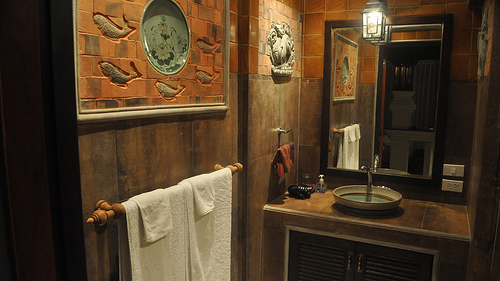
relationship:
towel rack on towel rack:
[88, 162, 244, 226] [82, 160, 250, 234]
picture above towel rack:
[70, 2, 233, 128] [82, 160, 250, 234]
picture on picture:
[72, 2, 230, 123] [70, 2, 233, 128]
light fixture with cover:
[359, 4, 390, 45] [355, 0, 390, 44]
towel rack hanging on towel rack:
[275, 127, 296, 151] [267, 127, 298, 152]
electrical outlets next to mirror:
[442, 179, 463, 193] [320, 18, 442, 192]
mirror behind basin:
[320, 18, 442, 192] [333, 185, 403, 219]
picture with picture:
[70, 2, 233, 128] [72, 2, 230, 123]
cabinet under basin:
[276, 222, 442, 280] [333, 185, 403, 219]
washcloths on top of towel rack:
[125, 169, 223, 240] [88, 162, 244, 226]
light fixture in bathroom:
[359, 4, 390, 45] [2, 2, 499, 280]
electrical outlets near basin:
[441, 181, 464, 193] [333, 185, 403, 219]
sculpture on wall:
[266, 23, 296, 76] [251, 0, 303, 281]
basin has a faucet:
[333, 185, 403, 219] [359, 165, 377, 206]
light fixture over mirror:
[359, 4, 390, 45] [320, 18, 442, 192]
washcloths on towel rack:
[125, 169, 223, 240] [82, 160, 250, 234]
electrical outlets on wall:
[441, 181, 464, 193] [297, 0, 469, 210]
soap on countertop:
[312, 173, 329, 194] [257, 183, 477, 240]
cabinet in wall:
[276, 222, 442, 280] [297, 0, 469, 210]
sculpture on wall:
[264, 18, 297, 89] [251, 0, 303, 281]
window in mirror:
[376, 42, 435, 130] [320, 18, 442, 192]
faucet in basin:
[359, 165, 377, 206] [333, 185, 403, 219]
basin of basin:
[329, 181, 405, 218] [333, 185, 403, 219]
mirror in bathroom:
[320, 18, 442, 192] [2, 2, 499, 280]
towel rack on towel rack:
[275, 127, 296, 151] [267, 127, 298, 152]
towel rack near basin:
[275, 127, 296, 151] [333, 185, 403, 219]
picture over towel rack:
[70, 2, 233, 128] [88, 162, 244, 226]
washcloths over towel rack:
[125, 169, 223, 240] [88, 162, 244, 226]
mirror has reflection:
[320, 18, 442, 192] [328, 28, 434, 179]